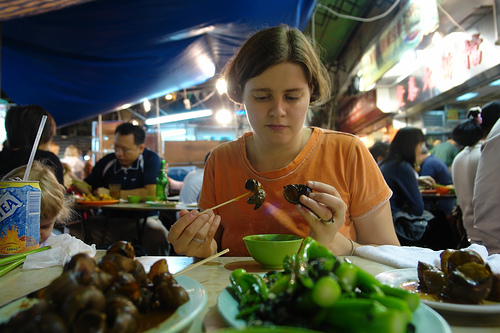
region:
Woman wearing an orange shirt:
[185, 19, 405, 267]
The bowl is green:
[233, 220, 320, 272]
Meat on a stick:
[176, 181, 278, 223]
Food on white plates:
[53, 192, 484, 329]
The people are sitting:
[8, 85, 179, 238]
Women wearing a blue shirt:
[383, 116, 446, 236]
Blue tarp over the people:
[6, 4, 321, 124]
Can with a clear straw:
[1, 108, 71, 253]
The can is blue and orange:
[6, 175, 50, 260]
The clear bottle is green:
[153, 152, 173, 208]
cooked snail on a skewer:
[241, 178, 266, 213]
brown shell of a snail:
[277, 180, 314, 211]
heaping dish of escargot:
[34, 231, 180, 331]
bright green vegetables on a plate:
[234, 247, 426, 332]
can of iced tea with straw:
[0, 115, 43, 260]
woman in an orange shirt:
[191, 20, 385, 256]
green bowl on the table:
[240, 230, 308, 269]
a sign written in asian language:
[381, 52, 484, 109]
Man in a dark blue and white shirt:
[77, 122, 170, 202]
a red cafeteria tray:
[67, 190, 120, 208]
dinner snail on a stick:
[242, 175, 269, 215]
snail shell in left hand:
[277, 177, 320, 208]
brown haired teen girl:
[155, 21, 415, 268]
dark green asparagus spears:
[220, 235, 445, 328]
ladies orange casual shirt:
[190, 122, 404, 263]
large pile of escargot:
[7, 230, 205, 332]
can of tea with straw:
[3, 105, 58, 260]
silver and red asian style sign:
[388, 24, 488, 116]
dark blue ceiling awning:
[5, 1, 302, 139]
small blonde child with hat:
[2, 133, 77, 269]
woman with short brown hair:
[215, 26, 355, 161]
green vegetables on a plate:
[224, 230, 454, 331]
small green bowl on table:
[242, 227, 307, 269]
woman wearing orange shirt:
[173, 15, 408, 257]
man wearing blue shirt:
[88, 110, 171, 193]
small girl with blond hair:
[18, 162, 70, 239]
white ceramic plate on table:
[366, 243, 498, 315]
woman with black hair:
[377, 116, 437, 216]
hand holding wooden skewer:
[161, 178, 272, 257]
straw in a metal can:
[1, 100, 56, 271]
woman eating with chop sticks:
[172, 24, 399, 248]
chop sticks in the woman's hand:
[202, 173, 264, 209]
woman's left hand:
[280, 179, 347, 254]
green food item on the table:
[215, 236, 452, 331]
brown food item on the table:
[2, 238, 209, 330]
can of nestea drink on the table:
[0, 179, 42, 254]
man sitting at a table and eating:
[80, 120, 165, 200]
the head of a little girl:
[0, 160, 94, 261]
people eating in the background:
[376, 120, 498, 248]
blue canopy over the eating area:
[2, 0, 309, 123]